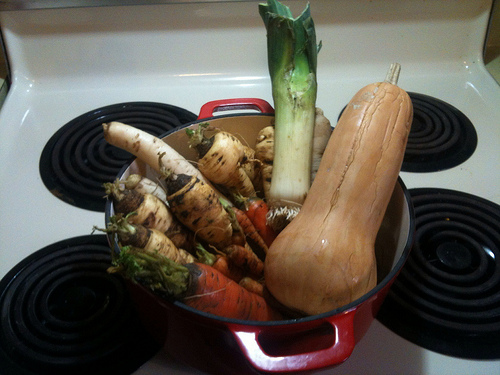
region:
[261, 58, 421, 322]
Squash in a pot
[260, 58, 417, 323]
Squash is in a pot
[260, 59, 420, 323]
Squash in a red pot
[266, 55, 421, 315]
Squash is in a red pot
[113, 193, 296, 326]
Carrots in a pot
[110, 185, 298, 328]
Carrots are in a pot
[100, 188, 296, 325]
Carrots in a red pot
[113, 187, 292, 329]
Carrots are in a red pot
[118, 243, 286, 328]
Carrot in a red pot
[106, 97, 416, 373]
Cooking pot sitting on the stove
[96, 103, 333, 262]
Bunch of whole parsnips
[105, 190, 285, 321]
Group of orange carrots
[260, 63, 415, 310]
Tan squash with a stem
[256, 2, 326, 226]
Green and white vegetable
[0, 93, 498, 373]
Black stove top burners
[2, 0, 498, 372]
White stove with black burners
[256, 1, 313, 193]
Small veggie in a red pot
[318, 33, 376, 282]
Small veggie in a red pot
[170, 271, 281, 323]
Small veggie in a red pot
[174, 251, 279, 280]
Small veggie in a red pot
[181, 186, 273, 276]
Small veggie in a red pot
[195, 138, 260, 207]
Small veggie in a red pot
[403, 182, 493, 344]
Black burner on a stove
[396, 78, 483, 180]
Black burner on a stove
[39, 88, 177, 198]
Black burner on a stove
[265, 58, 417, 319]
vegetable sits in pot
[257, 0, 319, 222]
vegetable sits in pot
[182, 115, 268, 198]
vegetable sits in pot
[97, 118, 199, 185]
vegetable sits in pot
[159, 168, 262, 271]
vegetable sits in pot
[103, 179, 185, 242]
vegetable sits in pot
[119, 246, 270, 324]
vegetable sits in pot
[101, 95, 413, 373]
pot contains vegetables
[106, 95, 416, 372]
pot sits on stove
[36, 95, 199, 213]
back burner is available since there are no pots or pans on it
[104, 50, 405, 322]
vegetables in a bowl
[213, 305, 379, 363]
the handle of the pot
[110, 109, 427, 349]
a red pot on the stove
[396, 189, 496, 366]
the burner on the stove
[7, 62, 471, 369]
the range on the stove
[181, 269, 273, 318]
a carrot in the pot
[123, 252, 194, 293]
the leaf on the carrot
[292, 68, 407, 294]
a squash in the pot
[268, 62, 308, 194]
a green vegetable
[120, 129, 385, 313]
vegetables